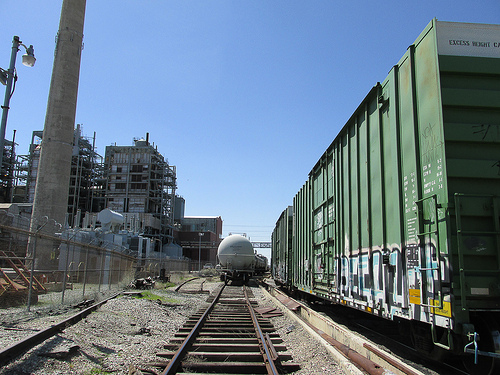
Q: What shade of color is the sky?
A: Blue.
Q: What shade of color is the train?
A: Green.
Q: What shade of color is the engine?
A: Gray.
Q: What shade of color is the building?
A: Gray.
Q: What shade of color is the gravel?
A: Gray.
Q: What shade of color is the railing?
A: Gray.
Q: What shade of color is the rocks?
A: Gray.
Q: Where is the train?
A: On the tracks.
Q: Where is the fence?
A: On the left.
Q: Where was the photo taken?
A: At a plant.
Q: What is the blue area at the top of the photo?
A: The sky.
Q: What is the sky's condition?
A: Clear.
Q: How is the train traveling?
A: On the tracks.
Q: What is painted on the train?
A: Graffiti.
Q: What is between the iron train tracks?
A: Wood.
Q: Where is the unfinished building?
A: In the space behind the train tracks.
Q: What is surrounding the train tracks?
A: A chain link fence.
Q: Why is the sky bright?
A: The sun is out.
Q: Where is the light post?
A: Next to the fence.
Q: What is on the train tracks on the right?
A: A boxcar.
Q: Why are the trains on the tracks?
A: Traveling.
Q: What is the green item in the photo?
A: Train.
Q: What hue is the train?
A: Green.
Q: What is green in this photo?
A: Train.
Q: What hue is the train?
A: Green.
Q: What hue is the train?
A: Green.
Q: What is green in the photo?
A: Train.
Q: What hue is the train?
A: What is green in the photo?.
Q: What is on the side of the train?
A: Graffiti.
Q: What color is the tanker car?
A: White.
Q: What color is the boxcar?
A: Green.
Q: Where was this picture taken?
A: On train tracks.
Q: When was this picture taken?
A: Day time.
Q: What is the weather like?
A: Sunny.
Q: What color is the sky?
A: Blue.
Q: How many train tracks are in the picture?
A: Two.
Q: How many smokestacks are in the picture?
A: One.